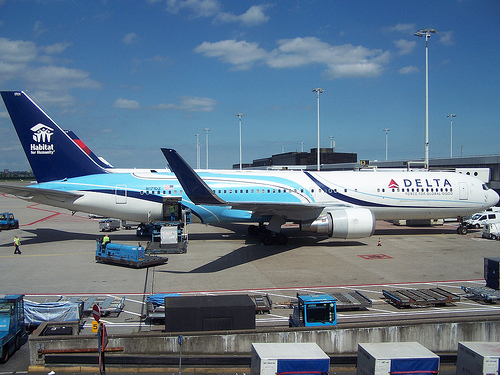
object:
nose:
[484, 182, 500, 210]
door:
[458, 182, 469, 201]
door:
[115, 184, 128, 204]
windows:
[140, 188, 453, 196]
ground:
[0, 179, 499, 333]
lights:
[312, 88, 325, 94]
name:
[403, 179, 451, 187]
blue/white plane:
[3, 90, 498, 246]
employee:
[99, 233, 110, 252]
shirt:
[13, 238, 19, 246]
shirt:
[102, 237, 109, 245]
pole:
[317, 91, 320, 170]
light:
[312, 88, 324, 93]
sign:
[93, 304, 100, 322]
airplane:
[5, 74, 499, 264]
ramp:
[145, 197, 192, 254]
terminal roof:
[233, 148, 358, 169]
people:
[168, 203, 175, 221]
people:
[138, 241, 143, 247]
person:
[13, 235, 22, 254]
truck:
[289, 292, 338, 327]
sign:
[30, 123, 55, 154]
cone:
[377, 238, 382, 246]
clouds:
[192, 37, 419, 81]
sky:
[0, 0, 498, 172]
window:
[267, 189, 270, 193]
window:
[278, 189, 281, 193]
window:
[344, 189, 347, 193]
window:
[311, 189, 314, 193]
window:
[301, 189, 304, 193]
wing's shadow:
[157, 245, 304, 274]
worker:
[102, 233, 111, 248]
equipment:
[95, 243, 168, 269]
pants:
[15, 244, 22, 253]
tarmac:
[358, 253, 393, 259]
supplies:
[160, 226, 178, 244]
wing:
[159, 148, 325, 233]